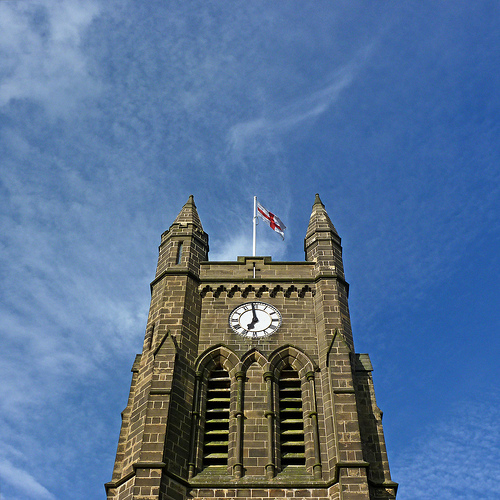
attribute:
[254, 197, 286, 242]
flag — red, white, waving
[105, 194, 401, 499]
building — brick, brown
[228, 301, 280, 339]
clock — round, white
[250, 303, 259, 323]
minute hand — black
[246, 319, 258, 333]
hour hand — black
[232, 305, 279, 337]
roman numerals — black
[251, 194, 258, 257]
pole — white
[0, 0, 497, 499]
sky — blue, white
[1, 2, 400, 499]
clouds — thin, white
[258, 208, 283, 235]
cross — red